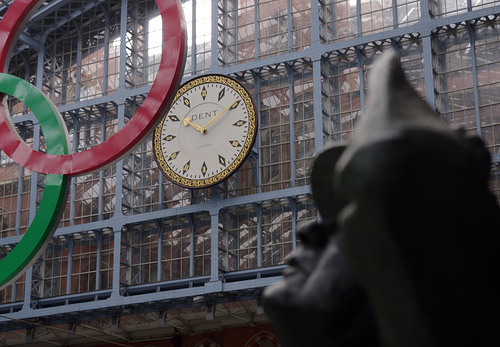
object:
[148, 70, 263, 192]
clock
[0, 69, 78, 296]
ring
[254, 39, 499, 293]
statue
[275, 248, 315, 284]
lip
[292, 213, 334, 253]
nose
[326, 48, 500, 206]
elbow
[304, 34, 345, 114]
metal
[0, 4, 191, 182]
circle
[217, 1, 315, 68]
window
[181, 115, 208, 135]
hand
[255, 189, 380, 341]
face